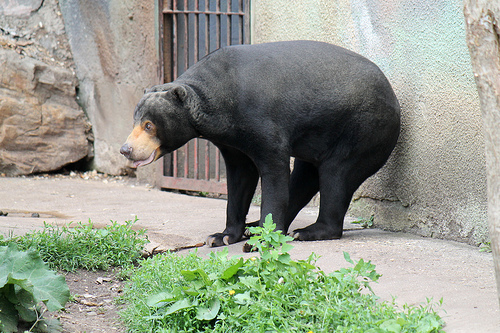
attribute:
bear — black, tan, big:
[122, 38, 403, 253]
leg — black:
[203, 167, 256, 252]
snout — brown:
[121, 143, 135, 156]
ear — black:
[176, 83, 191, 101]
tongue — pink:
[126, 162, 140, 173]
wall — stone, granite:
[373, 20, 459, 58]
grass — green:
[48, 231, 135, 277]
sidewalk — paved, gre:
[57, 194, 135, 215]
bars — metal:
[167, 13, 246, 37]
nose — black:
[118, 139, 135, 158]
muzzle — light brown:
[134, 133, 147, 148]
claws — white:
[207, 234, 230, 247]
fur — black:
[220, 122, 267, 146]